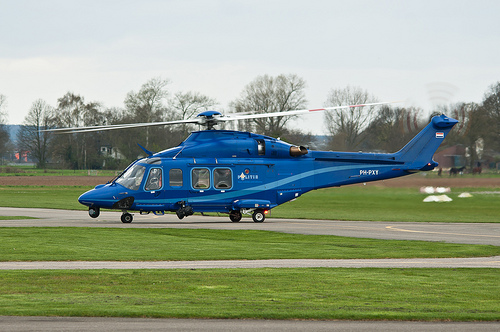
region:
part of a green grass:
[253, 265, 285, 298]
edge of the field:
[286, 305, 311, 321]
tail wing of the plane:
[422, 100, 460, 165]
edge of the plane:
[336, 160, 392, 195]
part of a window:
[202, 163, 229, 188]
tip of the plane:
[65, 171, 96, 217]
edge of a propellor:
[156, 117, 197, 135]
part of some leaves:
[125, 72, 185, 111]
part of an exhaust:
[284, 138, 314, 162]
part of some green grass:
[246, 274, 295, 313]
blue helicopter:
[75, 91, 461, 240]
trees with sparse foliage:
[21, 67, 306, 169]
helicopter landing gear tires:
[113, 197, 268, 229]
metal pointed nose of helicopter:
[76, 174, 119, 229]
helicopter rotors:
[31, 78, 405, 143]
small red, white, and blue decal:
[427, 125, 450, 145]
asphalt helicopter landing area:
[32, 201, 497, 254]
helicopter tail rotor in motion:
[400, 85, 470, 150]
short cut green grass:
[38, 230, 284, 256]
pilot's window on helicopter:
[139, 163, 166, 195]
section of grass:
[361, 276, 413, 304]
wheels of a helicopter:
[252, 213, 267, 221]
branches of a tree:
[353, 112, 382, 130]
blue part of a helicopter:
[242, 165, 272, 194]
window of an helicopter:
[198, 171, 205, 186]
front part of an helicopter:
[84, 191, 101, 215]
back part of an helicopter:
[390, 161, 415, 183]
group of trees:
[48, 148, 62, 155]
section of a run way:
[416, 224, 432, 236]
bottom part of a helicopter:
[263, 197, 283, 215]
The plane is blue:
[64, 105, 446, 251]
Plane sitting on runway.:
[90, 108, 467, 251]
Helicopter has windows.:
[186, 160, 248, 196]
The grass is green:
[62, 255, 312, 330]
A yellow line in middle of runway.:
[386, 212, 498, 247]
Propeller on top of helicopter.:
[121, 103, 276, 143]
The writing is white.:
[353, 163, 391, 188]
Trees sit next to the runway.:
[40, 103, 175, 149]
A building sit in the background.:
[7, 120, 84, 170]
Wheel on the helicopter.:
[106, 208, 265, 227]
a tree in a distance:
[18, 97, 58, 170]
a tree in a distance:
[49, 89, 91, 159]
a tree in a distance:
[0, 91, 16, 173]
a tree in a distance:
[124, 73, 176, 150]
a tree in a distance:
[164, 89, 211, 140]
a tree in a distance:
[236, 67, 313, 145]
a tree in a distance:
[318, 85, 377, 154]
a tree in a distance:
[368, 93, 400, 149]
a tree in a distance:
[476, 85, 499, 162]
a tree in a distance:
[387, 102, 414, 161]